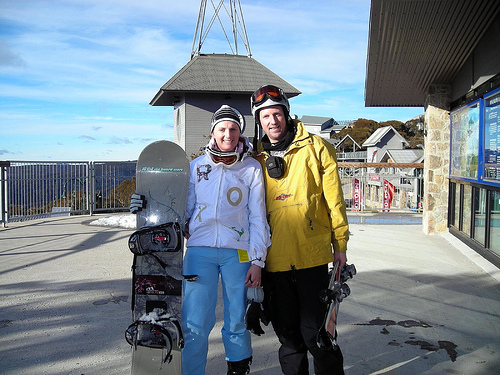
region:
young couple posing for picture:
[40, 32, 495, 373]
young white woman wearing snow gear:
[187, 84, 253, 374]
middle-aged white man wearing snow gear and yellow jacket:
[246, 78, 354, 373]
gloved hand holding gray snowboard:
[127, 105, 194, 372]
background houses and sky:
[332, 77, 462, 254]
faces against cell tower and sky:
[158, 6, 344, 192]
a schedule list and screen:
[437, 75, 497, 206]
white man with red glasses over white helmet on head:
[237, 86, 315, 148]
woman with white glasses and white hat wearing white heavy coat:
[195, 101, 255, 181]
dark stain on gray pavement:
[357, 295, 469, 366]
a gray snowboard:
[87, 127, 207, 371]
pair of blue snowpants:
[170, 249, 270, 372]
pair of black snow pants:
[246, 214, 358, 366]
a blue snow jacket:
[170, 147, 287, 275]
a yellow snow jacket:
[243, 123, 370, 280]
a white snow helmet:
[233, 80, 305, 134]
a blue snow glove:
[125, 190, 148, 230]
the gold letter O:
[213, 172, 255, 218]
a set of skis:
[304, 200, 381, 359]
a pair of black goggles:
[242, 75, 304, 112]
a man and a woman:
[190, 84, 345, 370]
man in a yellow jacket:
[250, 85, 352, 274]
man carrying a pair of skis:
[250, 91, 362, 345]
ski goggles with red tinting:
[247, 84, 295, 112]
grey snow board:
[128, 136, 195, 373]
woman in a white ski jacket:
[176, 100, 270, 252]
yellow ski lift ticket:
[233, 239, 253, 269]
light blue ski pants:
[181, 239, 246, 374]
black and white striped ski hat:
[208, 100, 248, 132]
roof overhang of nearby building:
[363, 1, 492, 110]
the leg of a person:
[224, 257, 256, 369]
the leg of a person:
[176, 255, 213, 370]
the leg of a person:
[295, 260, 342, 370]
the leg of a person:
[253, 278, 305, 372]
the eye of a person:
[273, 110, 282, 117]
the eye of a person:
[261, 111, 271, 121]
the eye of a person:
[228, 127, 236, 134]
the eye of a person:
[216, 127, 227, 133]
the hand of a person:
[237, 172, 274, 311]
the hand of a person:
[319, 156, 351, 281]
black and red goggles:
[248, 86, 290, 103]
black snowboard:
[133, 139, 190, 373]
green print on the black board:
[140, 162, 185, 177]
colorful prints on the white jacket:
[188, 158, 272, 248]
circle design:
[223, 180, 252, 211]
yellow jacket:
[260, 141, 345, 268]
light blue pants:
[184, 249, 253, 362]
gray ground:
[4, 227, 126, 372]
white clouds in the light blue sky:
[1, 66, 143, 158]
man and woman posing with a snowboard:
[129, 85, 356, 374]